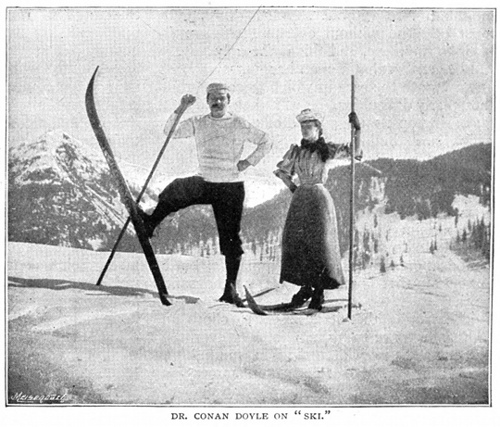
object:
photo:
[0, 8, 496, 407]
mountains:
[13, 130, 160, 253]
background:
[0, 0, 500, 427]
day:
[6, 6, 494, 405]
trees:
[447, 200, 463, 227]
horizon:
[2, 228, 490, 266]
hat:
[297, 108, 321, 120]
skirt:
[279, 182, 350, 289]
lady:
[275, 110, 363, 313]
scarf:
[296, 136, 329, 161]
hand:
[348, 110, 363, 128]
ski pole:
[344, 76, 363, 324]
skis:
[241, 289, 361, 317]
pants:
[130, 174, 254, 295]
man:
[137, 83, 272, 305]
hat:
[206, 83, 228, 95]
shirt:
[161, 112, 271, 186]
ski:
[83, 66, 171, 309]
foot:
[135, 204, 155, 242]